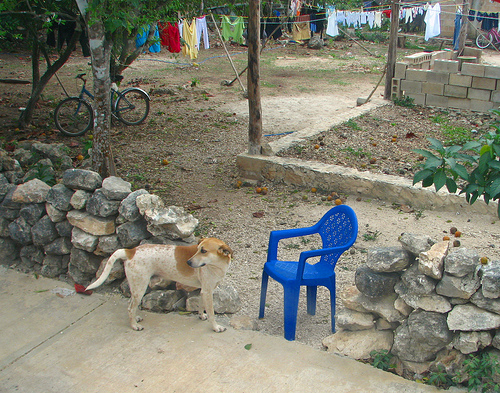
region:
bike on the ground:
[31, 58, 180, 154]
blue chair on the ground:
[241, 203, 366, 329]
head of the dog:
[176, 227, 235, 284]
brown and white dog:
[140, 220, 240, 297]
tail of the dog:
[73, 251, 134, 302]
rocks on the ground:
[236, 215, 266, 243]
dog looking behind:
[116, 230, 236, 325]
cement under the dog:
[128, 317, 198, 390]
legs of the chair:
[241, 282, 341, 349]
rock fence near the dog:
[347, 245, 472, 352]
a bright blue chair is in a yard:
[239, 154, 389, 346]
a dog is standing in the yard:
[78, 229, 240, 340]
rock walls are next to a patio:
[6, 164, 497, 370]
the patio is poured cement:
[3, 259, 463, 391]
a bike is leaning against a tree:
[48, 69, 154, 141]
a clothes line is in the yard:
[123, 0, 498, 62]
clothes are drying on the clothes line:
[128, 2, 464, 58]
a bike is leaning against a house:
[467, 20, 499, 53]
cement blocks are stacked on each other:
[386, 43, 499, 119]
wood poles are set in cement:
[228, 3, 476, 182]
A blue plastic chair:
[256, 201, 361, 341]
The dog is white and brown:
[82, 233, 235, 336]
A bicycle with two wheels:
[54, 68, 154, 139]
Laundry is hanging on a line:
[133, 0, 498, 61]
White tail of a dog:
[81, 244, 126, 295]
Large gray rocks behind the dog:
[2, 159, 243, 339]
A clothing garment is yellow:
[179, 14, 202, 63]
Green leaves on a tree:
[409, 105, 498, 206]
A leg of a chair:
[251, 272, 273, 321]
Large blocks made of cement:
[385, 48, 498, 119]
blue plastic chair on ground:
[240, 200, 365, 338]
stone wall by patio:
[328, 232, 488, 369]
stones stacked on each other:
[354, 236, 470, 366]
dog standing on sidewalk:
[81, 236, 236, 339]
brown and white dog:
[125, 233, 224, 280]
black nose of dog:
[181, 257, 198, 268]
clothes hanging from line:
[137, 9, 254, 57]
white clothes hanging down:
[327, 0, 448, 41]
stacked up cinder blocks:
[399, 56, 489, 106]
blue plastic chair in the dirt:
[233, 185, 362, 343]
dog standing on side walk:
[77, 226, 250, 349]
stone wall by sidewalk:
[328, 222, 498, 374]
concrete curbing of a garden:
[243, 141, 410, 198]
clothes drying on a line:
[148, 5, 246, 58]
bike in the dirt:
[50, 68, 166, 140]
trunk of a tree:
[16, 35, 67, 122]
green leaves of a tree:
[406, 108, 494, 213]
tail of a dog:
[81, 241, 126, 301]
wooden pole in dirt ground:
[241, 0, 281, 138]